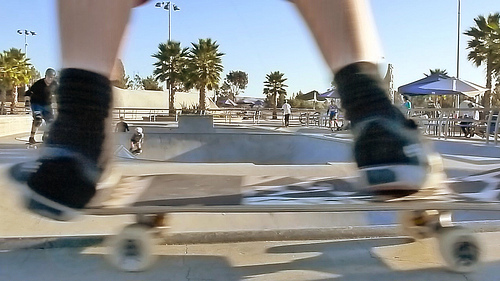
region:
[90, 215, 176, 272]
wheel on the skateboard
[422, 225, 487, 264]
the wheel is blurred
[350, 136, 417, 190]
back of the shoe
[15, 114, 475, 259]
person on the skateboard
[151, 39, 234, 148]
palm trees in skate park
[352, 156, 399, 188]
label on the shoe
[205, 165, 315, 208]
top of the skateboard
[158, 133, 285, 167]
ramp of the skatepark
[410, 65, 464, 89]
the tent is blue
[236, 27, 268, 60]
the sky is clear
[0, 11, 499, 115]
Palm trees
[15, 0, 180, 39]
Overhead lights for the skate park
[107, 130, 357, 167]
Skate park bowl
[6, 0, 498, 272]
Kids skateboarding at the park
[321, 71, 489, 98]
Blue sun canopies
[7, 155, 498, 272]
Black and white skateboard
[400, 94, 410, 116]
Man with teal shirt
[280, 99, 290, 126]
Man in white shirt and black pants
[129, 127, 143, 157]
Skateboarder in the bowl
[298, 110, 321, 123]
Bicycle parked outside of the skating area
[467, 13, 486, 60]
a palm tree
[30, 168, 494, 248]
a skateboard on the ground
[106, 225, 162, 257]
a white wheel on the skateboard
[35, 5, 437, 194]
a person wearing black shoes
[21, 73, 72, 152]
a man skateboarding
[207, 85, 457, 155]
people at a skate park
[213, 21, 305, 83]
the sky behind the trees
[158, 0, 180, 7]
a light post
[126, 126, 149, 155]
a person with a white helmet on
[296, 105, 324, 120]
a bicycle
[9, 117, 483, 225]
two feet on the skateboard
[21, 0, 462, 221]
legs are about shoulder width apart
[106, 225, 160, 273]
white wheel under the skateboard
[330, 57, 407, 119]
black socks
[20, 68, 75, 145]
person on a skateboard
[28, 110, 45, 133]
knee is bent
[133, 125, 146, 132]
helmet on the head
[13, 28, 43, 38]
three lights on the top of the pole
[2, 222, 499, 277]
shadows on the ground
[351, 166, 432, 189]
bottom of the shoe is white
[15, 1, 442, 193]
A person on a skateboard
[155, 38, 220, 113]
Trees near the skatepark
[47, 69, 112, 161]
The person is wearing a black sock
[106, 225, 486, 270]
Wheels on the skateboard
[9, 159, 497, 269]
A skateboard beneath the person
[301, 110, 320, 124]
A bicycle by the fence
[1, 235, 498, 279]
A shadow on the ground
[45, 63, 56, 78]
The person is wearing a helmet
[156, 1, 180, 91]
A lamp post near the trees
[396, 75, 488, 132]
An umbrella near the people